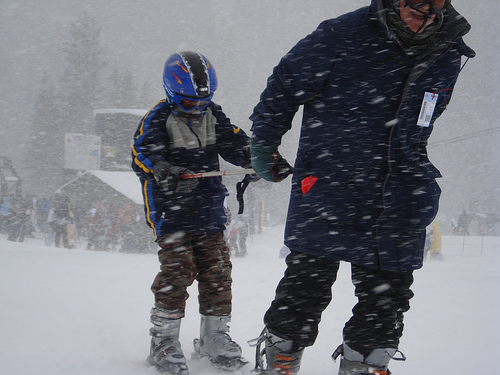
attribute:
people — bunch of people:
[0, 189, 250, 255]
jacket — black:
[254, 2, 476, 276]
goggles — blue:
[158, 87, 211, 113]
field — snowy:
[2, 240, 497, 372]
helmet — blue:
[156, 42, 224, 126]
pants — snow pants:
[153, 206, 235, 324]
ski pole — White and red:
[179, 164, 298, 179]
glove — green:
[246, 134, 285, 184]